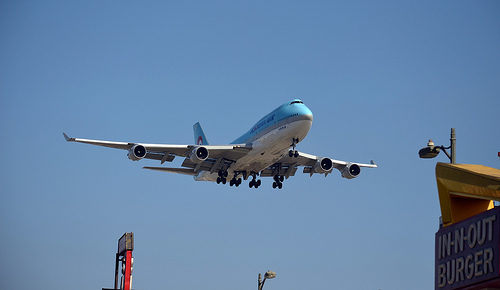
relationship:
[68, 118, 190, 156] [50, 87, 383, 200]
wing of plane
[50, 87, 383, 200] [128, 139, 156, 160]
plane has engine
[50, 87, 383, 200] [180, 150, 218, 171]
plane has engine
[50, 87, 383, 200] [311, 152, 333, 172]
plane has engine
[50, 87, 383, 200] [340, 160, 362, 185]
plane has engine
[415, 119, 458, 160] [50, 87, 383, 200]
light under plane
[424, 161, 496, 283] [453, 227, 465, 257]
sign has n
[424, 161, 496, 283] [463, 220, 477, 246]
sign has letter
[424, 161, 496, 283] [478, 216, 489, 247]
sign has letter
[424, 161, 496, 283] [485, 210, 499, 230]
sign has letter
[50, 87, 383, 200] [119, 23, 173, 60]
plane in sky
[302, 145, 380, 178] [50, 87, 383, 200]
wing of plane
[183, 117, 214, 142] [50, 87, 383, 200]
tail of plane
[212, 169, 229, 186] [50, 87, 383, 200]
wheel of plane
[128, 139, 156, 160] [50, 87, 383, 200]
engine of plane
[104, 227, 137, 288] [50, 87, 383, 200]
isgn below plane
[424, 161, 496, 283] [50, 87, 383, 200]
sign near plane